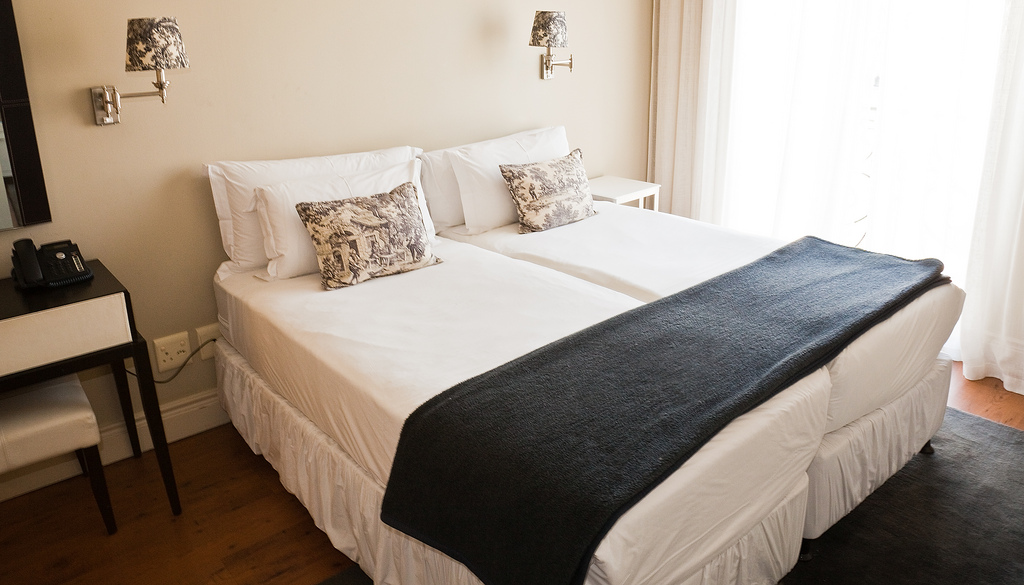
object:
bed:
[202, 126, 968, 585]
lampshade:
[126, 16, 191, 72]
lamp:
[124, 16, 189, 89]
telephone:
[11, 238, 94, 290]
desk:
[0, 258, 184, 515]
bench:
[0, 372, 120, 535]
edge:
[0, 414, 101, 470]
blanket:
[380, 236, 950, 585]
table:
[588, 175, 661, 211]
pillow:
[295, 182, 443, 292]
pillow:
[262, 184, 431, 262]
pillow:
[206, 152, 438, 263]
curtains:
[655, 0, 735, 226]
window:
[722, 0, 1022, 356]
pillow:
[302, 186, 439, 282]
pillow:
[499, 148, 598, 234]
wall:
[0, 1, 659, 318]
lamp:
[529, 10, 568, 66]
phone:
[11, 238, 93, 291]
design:
[296, 182, 444, 290]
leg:
[132, 342, 182, 515]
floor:
[0, 463, 315, 585]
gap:
[800, 361, 836, 540]